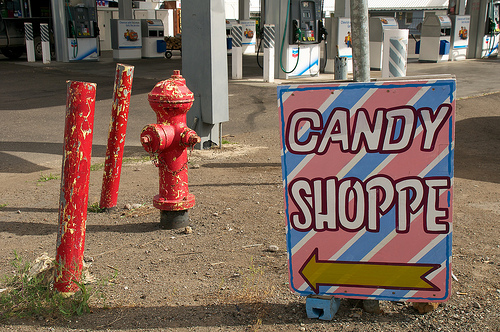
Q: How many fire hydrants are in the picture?
A: One.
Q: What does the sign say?
A: Candy shoppe.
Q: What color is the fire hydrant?
A: Red.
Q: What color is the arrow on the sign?
A: Yellow.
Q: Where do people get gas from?
A: Gas station.